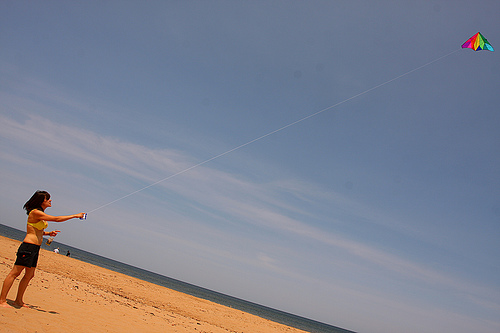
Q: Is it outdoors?
A: Yes, it is outdoors.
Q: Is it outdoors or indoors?
A: It is outdoors.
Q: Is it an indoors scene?
A: No, it is outdoors.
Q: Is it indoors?
A: No, it is outdoors.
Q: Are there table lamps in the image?
A: No, there are no table lamps.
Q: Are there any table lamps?
A: No, there are no table lamps.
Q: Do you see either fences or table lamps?
A: No, there are no table lamps or fences.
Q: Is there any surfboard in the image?
A: No, there are no surfboards.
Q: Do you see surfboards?
A: No, there are no surfboards.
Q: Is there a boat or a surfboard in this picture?
A: No, there are no surfboards or boats.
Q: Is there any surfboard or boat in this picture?
A: No, there are no surfboards or boats.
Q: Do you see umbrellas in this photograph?
A: No, there are no umbrellas.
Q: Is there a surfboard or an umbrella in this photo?
A: No, there are no umbrellas or surfboards.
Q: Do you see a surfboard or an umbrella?
A: No, there are no umbrellas or surfboards.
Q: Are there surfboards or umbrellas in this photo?
A: No, there are no umbrellas or surfboards.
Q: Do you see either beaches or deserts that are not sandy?
A: No, there is a beach but it is sandy.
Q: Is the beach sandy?
A: Yes, the beach is sandy.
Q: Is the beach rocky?
A: No, the beach is sandy.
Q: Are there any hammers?
A: No, there are no hammers.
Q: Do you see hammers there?
A: No, there are no hammers.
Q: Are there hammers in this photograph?
A: No, there are no hammers.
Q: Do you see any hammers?
A: No, there are no hammers.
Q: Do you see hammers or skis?
A: No, there are no hammers or skis.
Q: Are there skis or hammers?
A: No, there are no hammers or skis.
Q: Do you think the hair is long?
A: Yes, the hair is long.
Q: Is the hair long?
A: Yes, the hair is long.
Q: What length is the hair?
A: The hair is long.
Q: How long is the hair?
A: The hair is long.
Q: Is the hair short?
A: No, the hair is long.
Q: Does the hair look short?
A: No, the hair is long.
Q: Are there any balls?
A: No, there are no balls.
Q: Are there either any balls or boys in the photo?
A: No, there are no balls or boys.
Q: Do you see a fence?
A: No, there are no fences.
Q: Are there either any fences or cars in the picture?
A: No, there are no fences or cars.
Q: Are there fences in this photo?
A: No, there are no fences.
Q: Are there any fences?
A: No, there are no fences.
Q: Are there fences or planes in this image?
A: No, there are no fences or planes.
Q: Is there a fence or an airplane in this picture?
A: No, there are no fences or airplanes.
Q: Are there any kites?
A: Yes, there is a kite.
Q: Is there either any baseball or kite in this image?
A: Yes, there is a kite.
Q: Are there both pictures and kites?
A: No, there is a kite but no pictures.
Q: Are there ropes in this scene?
A: No, there are no ropes.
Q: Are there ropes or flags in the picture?
A: No, there are no ropes or flags.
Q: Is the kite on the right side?
A: Yes, the kite is on the right of the image.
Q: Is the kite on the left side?
A: No, the kite is on the right of the image.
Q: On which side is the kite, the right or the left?
A: The kite is on the right of the image.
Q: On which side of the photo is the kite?
A: The kite is on the right of the image.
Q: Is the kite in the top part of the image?
A: Yes, the kite is in the top of the image.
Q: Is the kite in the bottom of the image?
A: No, the kite is in the top of the image.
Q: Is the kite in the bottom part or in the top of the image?
A: The kite is in the top of the image.